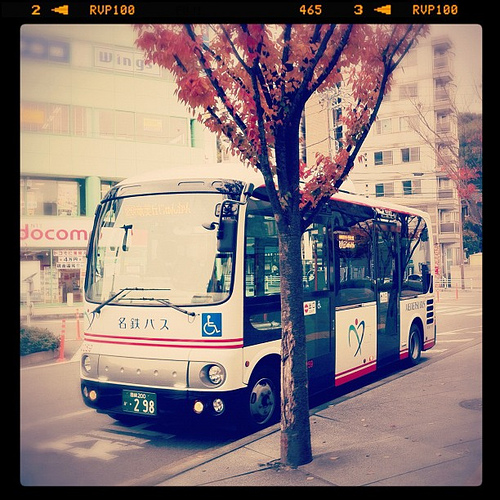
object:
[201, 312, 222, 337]
sign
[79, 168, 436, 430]
bus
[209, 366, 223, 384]
headlight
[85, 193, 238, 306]
windshield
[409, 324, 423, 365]
wheel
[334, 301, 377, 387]
ad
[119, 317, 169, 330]
text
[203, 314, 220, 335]
handicapped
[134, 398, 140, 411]
number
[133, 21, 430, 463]
tree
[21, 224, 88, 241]
sign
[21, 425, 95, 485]
street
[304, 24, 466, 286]
building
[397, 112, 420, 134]
window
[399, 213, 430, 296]
window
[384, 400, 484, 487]
sidewalk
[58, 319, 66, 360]
cone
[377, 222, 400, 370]
door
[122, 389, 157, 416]
license plate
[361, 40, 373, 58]
leaf